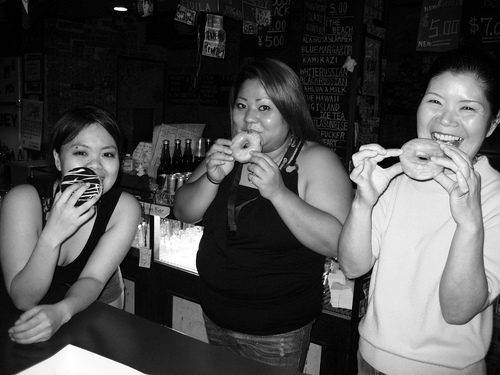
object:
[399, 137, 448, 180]
doughnut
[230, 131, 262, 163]
doughnut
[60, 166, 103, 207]
doughnut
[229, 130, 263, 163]
snack1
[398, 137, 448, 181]
snack2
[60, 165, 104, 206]
snack3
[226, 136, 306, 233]
lanyard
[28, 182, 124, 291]
top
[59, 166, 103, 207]
donut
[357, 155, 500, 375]
shirt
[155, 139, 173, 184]
beer bottle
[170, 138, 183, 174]
beer bottle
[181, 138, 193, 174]
beer bottle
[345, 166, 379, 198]
ground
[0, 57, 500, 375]
ladies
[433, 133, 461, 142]
teeth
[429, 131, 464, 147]
mouth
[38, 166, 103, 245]
donut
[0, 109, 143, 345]
woman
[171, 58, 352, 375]
woman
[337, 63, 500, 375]
woman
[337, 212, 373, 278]
elbow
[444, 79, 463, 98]
lay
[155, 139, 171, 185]
bottle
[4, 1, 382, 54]
wall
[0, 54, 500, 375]
women donuts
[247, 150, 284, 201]
hand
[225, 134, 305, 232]
scarf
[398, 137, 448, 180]
donut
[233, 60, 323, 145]
hair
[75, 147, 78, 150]
dot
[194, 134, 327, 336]
blouse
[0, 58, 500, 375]
people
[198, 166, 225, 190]
wrist band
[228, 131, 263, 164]
donut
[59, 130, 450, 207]
donuts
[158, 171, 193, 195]
row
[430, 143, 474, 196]
fingers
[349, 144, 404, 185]
fingers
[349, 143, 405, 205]
hand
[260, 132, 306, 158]
neck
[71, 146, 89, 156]
eyelid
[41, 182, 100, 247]
hand